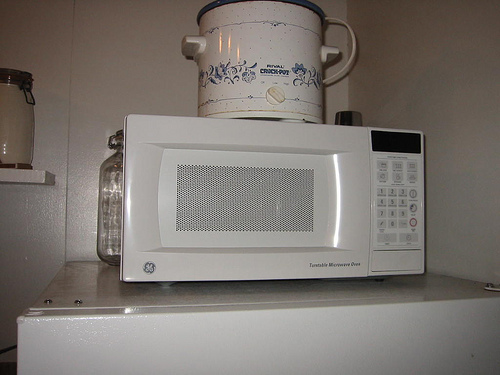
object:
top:
[125, 110, 426, 131]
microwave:
[118, 113, 433, 286]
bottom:
[95, 268, 436, 296]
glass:
[1, 65, 35, 170]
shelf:
[1, 167, 55, 187]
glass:
[95, 126, 123, 272]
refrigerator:
[13, 259, 494, 374]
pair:
[126, 1, 430, 279]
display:
[370, 131, 423, 154]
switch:
[262, 86, 288, 108]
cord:
[322, 16, 358, 85]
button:
[372, 250, 423, 272]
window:
[175, 164, 318, 232]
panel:
[373, 151, 424, 249]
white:
[39, 262, 497, 302]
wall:
[1, 4, 498, 375]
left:
[34, 104, 121, 306]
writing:
[307, 260, 364, 269]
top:
[16, 261, 499, 317]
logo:
[258, 63, 291, 77]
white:
[2, 84, 33, 165]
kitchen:
[3, 3, 495, 374]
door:
[119, 112, 372, 283]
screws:
[42, 298, 55, 305]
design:
[196, 57, 325, 108]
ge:
[142, 260, 157, 275]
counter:
[16, 258, 500, 375]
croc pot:
[178, 0, 364, 122]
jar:
[94, 127, 142, 270]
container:
[0, 63, 36, 169]